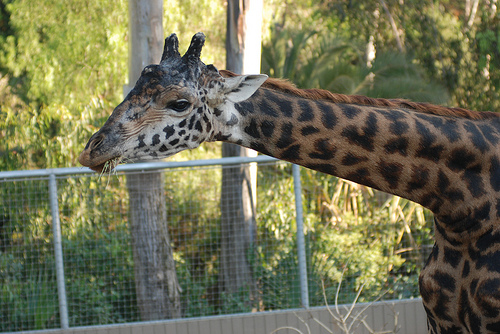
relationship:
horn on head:
[182, 26, 205, 60] [77, 32, 220, 177]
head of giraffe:
[77, 32, 220, 177] [1, 74, 398, 281]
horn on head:
[156, 34, 181, 61] [77, 32, 220, 177]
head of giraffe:
[77, 32, 220, 177] [75, 32, 497, 332]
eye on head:
[167, 98, 193, 112] [77, 30, 220, 175]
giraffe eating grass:
[75, 32, 497, 332] [95, 155, 128, 190]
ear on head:
[222, 72, 272, 103] [77, 32, 220, 177]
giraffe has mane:
[75, 32, 497, 332] [213, 65, 498, 122]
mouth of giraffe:
[76, 151, 131, 172] [75, 32, 497, 332]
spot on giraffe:
[177, 116, 191, 133] [75, 32, 497, 332]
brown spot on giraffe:
[165, 133, 182, 156] [115, 88, 474, 275]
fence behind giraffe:
[1, 150, 309, 332] [75, 32, 497, 332]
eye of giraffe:
[167, 98, 193, 112] [78, 29, 466, 266]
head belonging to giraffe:
[77, 32, 220, 177] [75, 32, 497, 332]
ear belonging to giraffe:
[222, 70, 272, 106] [75, 32, 497, 332]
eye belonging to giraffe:
[167, 98, 191, 110] [75, 32, 497, 332]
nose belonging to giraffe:
[81, 130, 107, 152] [38, 31, 498, 312]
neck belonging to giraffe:
[241, 68, 438, 203] [75, 32, 497, 332]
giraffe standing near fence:
[75, 32, 497, 332] [8, 147, 429, 332]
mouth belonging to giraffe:
[73, 151, 128, 172] [75, 32, 497, 332]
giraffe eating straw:
[75, 32, 497, 332] [90, 158, 114, 188]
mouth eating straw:
[73, 151, 128, 172] [90, 158, 114, 188]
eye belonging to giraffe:
[167, 98, 193, 112] [108, 56, 235, 147]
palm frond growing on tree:
[360, 79, 446, 106] [278, 8, 458, 166]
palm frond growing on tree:
[256, 27, 452, 104] [278, 8, 458, 166]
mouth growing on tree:
[76, 151, 131, 172] [278, 8, 458, 166]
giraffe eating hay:
[75, 32, 497, 332] [95, 155, 122, 187]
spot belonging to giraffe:
[339, 110, 382, 154] [65, 22, 498, 242]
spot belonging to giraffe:
[308, 136, 339, 162] [67, 39, 493, 218]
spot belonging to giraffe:
[296, 97, 316, 125] [104, 40, 470, 247]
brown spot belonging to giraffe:
[250, 90, 498, 332] [75, 32, 497, 332]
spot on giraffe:
[317, 107, 343, 142] [122, 44, 437, 191]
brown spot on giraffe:
[444, 145, 477, 177] [58, 31, 491, 271]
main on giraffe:
[219, 69, 499, 121] [75, 32, 497, 332]